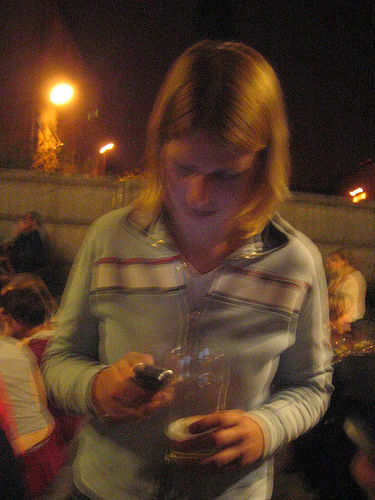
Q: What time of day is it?
A: Night time.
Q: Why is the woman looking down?
A: Texting.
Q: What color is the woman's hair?
A: Blonde.